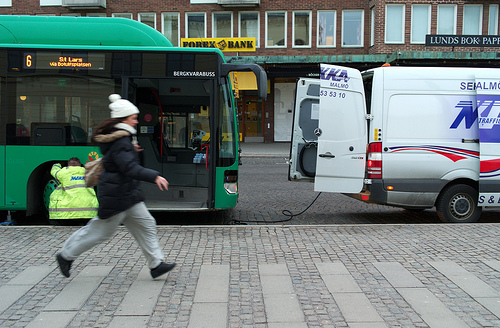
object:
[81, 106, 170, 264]
woman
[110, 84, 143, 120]
hat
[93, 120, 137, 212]
jacket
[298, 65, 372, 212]
doors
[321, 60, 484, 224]
van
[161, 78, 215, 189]
door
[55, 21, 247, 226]
bus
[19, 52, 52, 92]
numbers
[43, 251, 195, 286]
shoes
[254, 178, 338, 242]
cable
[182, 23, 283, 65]
sign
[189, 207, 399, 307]
sidewalk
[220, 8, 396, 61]
windows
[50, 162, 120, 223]
coat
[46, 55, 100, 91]
sign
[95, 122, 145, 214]
coat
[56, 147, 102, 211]
man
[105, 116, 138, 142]
parka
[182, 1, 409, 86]
building